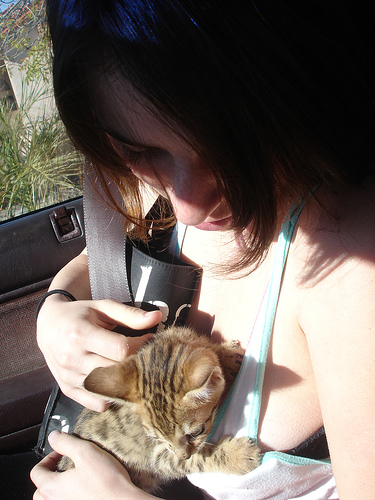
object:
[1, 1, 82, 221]
car window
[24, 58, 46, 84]
green leaves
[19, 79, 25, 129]
leaves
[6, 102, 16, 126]
leaves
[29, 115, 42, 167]
leaves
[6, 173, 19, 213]
leaves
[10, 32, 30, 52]
leaves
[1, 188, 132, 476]
door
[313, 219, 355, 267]
shadow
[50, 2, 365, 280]
hair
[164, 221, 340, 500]
shirt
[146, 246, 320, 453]
chest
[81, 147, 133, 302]
seatbelt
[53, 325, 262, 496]
cat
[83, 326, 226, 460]
head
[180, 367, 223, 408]
ear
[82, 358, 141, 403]
ear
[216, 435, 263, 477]
front paw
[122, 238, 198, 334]
object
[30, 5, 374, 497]
girl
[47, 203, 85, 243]
door lock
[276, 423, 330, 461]
bra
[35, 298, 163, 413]
hand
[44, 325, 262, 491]
kitten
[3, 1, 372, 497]
car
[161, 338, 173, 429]
stripe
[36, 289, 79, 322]
band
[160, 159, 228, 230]
nose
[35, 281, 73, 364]
woman's writs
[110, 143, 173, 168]
eye